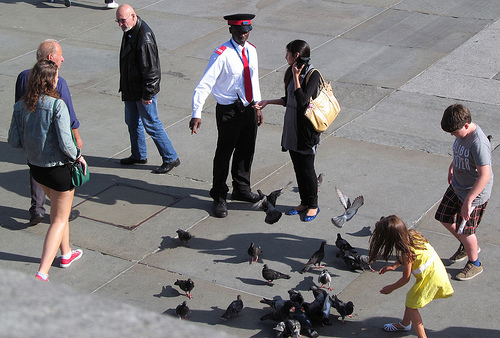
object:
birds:
[166, 268, 208, 299]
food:
[352, 307, 377, 331]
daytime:
[15, 13, 488, 334]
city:
[3, 11, 494, 334]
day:
[7, 13, 487, 333]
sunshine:
[32, 143, 264, 300]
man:
[186, 9, 265, 218]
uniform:
[189, 40, 267, 198]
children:
[435, 97, 496, 283]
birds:
[166, 220, 202, 249]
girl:
[362, 206, 458, 338]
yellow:
[397, 235, 459, 309]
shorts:
[429, 173, 491, 240]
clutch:
[68, 161, 94, 187]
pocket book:
[302, 68, 343, 138]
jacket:
[111, 25, 161, 97]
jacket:
[3, 93, 89, 165]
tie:
[237, 47, 257, 106]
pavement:
[29, 267, 140, 328]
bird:
[326, 181, 366, 230]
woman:
[261, 35, 331, 219]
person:
[109, 1, 183, 178]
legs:
[116, 95, 183, 174]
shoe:
[57, 246, 84, 269]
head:
[429, 97, 478, 141]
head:
[214, 8, 259, 49]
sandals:
[381, 319, 419, 336]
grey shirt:
[443, 129, 499, 207]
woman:
[1, 55, 90, 281]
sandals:
[283, 202, 323, 222]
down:
[413, 199, 442, 238]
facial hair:
[114, 11, 139, 35]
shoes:
[24, 267, 54, 283]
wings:
[333, 180, 354, 208]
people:
[5, 2, 263, 283]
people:
[4, 1, 495, 330]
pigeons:
[330, 291, 361, 323]